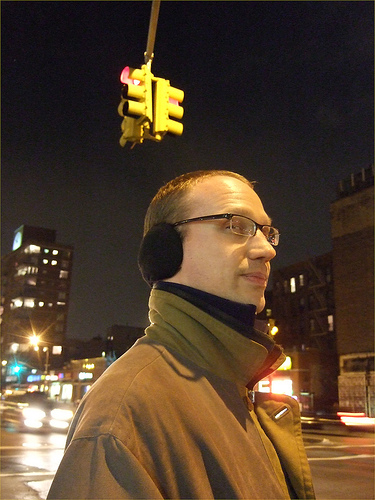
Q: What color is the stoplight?
A: Red.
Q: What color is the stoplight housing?
A: Yellow.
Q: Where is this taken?
A: Intersection.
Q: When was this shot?
A: Night time.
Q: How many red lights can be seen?
A: 2.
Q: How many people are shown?
A: 1.